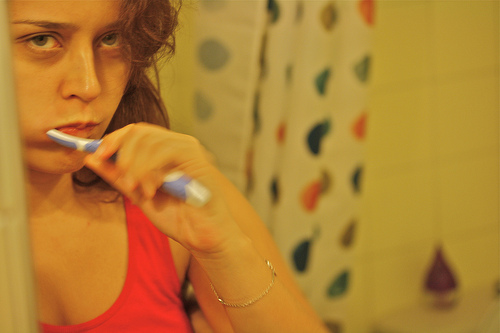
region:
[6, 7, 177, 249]
woman is brushing her teeth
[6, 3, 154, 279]
woman is brushing her teeth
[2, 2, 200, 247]
woman is brushing her teeth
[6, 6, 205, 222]
woman is brushing her teeth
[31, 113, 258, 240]
girl holding a toothbrush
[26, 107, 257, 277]
girl holding a toothbrush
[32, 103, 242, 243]
girl holding a toothbrush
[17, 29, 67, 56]
a girl's right eye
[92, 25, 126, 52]
a girl's left eye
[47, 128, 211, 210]
a blue and white toothbrush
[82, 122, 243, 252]
a girl's left hand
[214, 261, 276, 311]
a girl's silver bracelet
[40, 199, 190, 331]
a girl's red tank top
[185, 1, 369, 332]
a white shower curtain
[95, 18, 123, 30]
a girl's left eyebrow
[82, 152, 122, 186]
a girl's left thumb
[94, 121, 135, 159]
a girl's left index finger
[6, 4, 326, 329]
woman brushing her teeth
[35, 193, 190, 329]
the woman's red tank top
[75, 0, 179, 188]
the woman's curly red hair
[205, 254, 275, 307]
gold bracelet on the woman's wrist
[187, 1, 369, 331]
white shower curtain with colorful pattern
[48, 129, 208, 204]
a purple and white toothbrush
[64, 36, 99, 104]
the woman's nose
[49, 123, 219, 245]
the woman's hand holding the toothbrush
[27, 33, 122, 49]
the woman's eyes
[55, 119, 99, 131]
the woman's red lips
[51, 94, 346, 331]
this is a girl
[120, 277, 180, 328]
the tank is red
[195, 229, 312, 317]
this is a silver bracelet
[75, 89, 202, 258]
this is a toothbrush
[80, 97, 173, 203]
the toothbrush is purple and white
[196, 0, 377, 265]
a shower curtain behind the lady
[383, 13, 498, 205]
white tile on the wall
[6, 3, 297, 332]
a lady brushing her teeth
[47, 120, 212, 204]
the blue tooth brush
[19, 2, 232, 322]
a lady wearing a red shirt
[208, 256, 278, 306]
a bracelet on the arm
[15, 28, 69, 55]
the eye of the lady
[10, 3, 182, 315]
a girl wearing a tank top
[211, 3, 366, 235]
a polka dotted shower curtain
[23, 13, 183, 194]
a lady with curly hair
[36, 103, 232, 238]
this is a toothbrush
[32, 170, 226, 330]
she is wearing a red shirt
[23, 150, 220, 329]
this is a red tank top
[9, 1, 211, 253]
she has brown hair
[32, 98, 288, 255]
the toothbrush is white and purple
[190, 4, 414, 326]
this is a spotted shower curtain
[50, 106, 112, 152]
these are her lips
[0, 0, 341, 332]
Woman holding a toothbrush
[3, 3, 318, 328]
Woman holding blue toothbrush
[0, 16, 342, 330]
Woman wearing red top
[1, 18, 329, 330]
Woman with dark hair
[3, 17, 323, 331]
Woman with silver bracelet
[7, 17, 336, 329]
Woman grooming in mirror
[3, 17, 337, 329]
Woman looking at mirror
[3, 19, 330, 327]
Woman brushing her teeth in mirror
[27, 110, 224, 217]
Blue and white toothbrush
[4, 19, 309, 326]
Woman with green eyes.